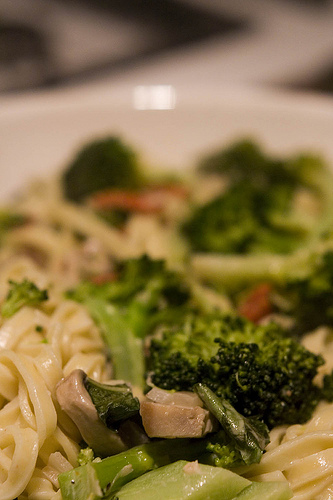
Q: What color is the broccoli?
A: Green.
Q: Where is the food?
A: On the plate.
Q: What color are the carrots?
A: Orange.